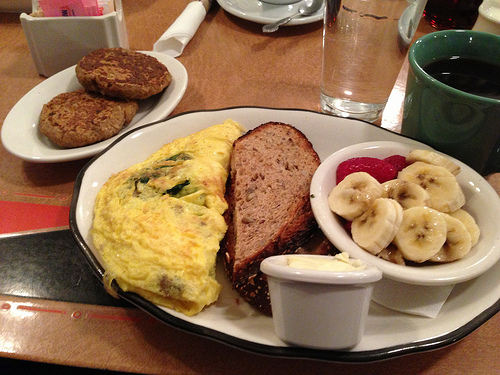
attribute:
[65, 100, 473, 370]
plate — white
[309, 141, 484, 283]
bowl — white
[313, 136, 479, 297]
bowl — white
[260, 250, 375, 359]
cup — white, little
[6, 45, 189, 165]
plate — small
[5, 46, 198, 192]
plate — white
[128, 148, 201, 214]
filling — dark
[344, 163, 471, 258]
bananas — yellow, slice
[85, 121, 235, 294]
omelet — yellow, egg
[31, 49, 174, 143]
sausage — brown, white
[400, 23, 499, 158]
cup — green, coffee, small, sauce, little, white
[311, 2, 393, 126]
glass — clear, water, empty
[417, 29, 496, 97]
rim — black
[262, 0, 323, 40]
spoon — metal, small, silver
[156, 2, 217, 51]
napkin — white, rolled up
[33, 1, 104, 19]
packets — sugar, pink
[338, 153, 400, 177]
strawberries — red, slice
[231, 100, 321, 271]
toast — brown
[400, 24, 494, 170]
mug — green, coffee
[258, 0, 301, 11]
bowl — white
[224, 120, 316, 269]
bread — whole wheat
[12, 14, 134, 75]
holder — sugar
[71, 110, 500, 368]
plate — white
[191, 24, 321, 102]
table — brown